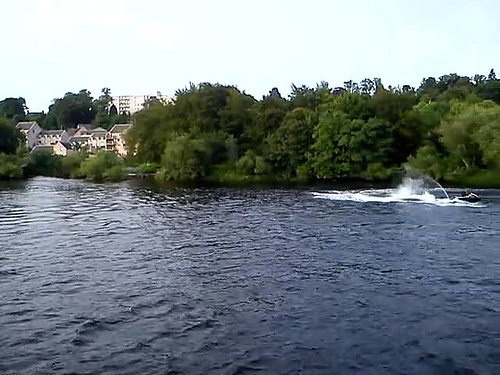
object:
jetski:
[389, 168, 455, 203]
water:
[0, 188, 395, 375]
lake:
[0, 207, 499, 373]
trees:
[151, 119, 276, 191]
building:
[104, 121, 142, 159]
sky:
[0, 0, 500, 68]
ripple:
[0, 202, 396, 363]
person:
[458, 187, 474, 200]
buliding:
[28, 128, 70, 158]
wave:
[305, 185, 428, 213]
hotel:
[88, 90, 182, 120]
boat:
[410, 183, 484, 207]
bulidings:
[89, 91, 175, 124]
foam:
[306, 174, 487, 210]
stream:
[155, 186, 449, 220]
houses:
[28, 127, 70, 158]